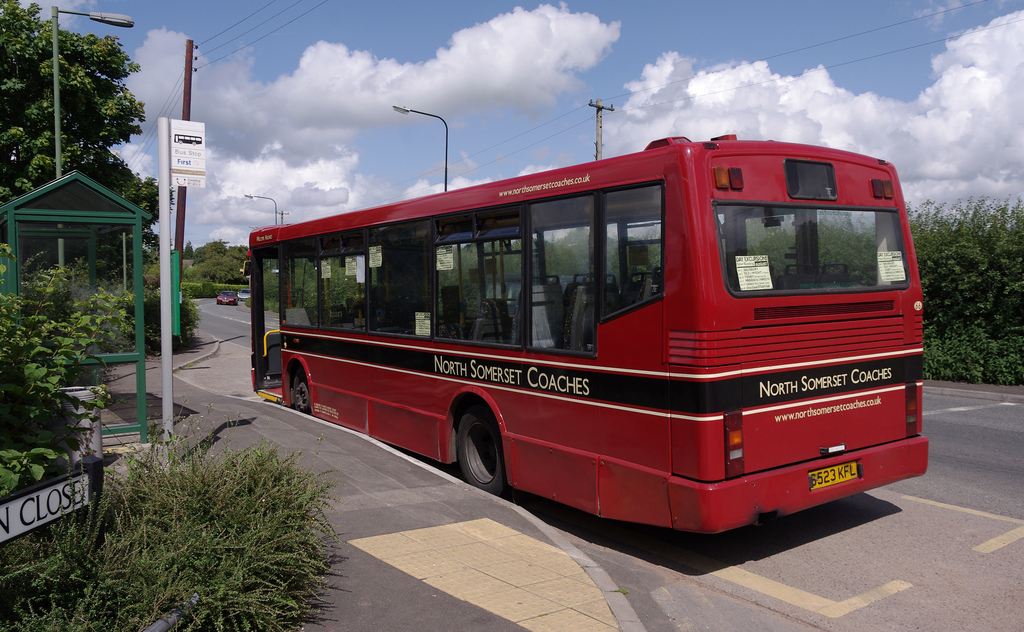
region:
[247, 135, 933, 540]
bus is red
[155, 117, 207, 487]
bus sign is attached to pole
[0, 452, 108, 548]
sign is inside of bushes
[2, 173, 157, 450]
bus stop bench is green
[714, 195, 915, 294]
window apart of bus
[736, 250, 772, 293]
paper is attached to bus window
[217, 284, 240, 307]
car is red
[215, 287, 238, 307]
red car driving on the road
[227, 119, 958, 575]
the bus is red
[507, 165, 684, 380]
a window of a bus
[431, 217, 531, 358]
a window of a bus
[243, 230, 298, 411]
the door on front the bus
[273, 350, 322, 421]
front wheel of a tire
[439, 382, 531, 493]
back wheel of a tire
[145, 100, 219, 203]
a sign on a pole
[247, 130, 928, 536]
red tour bus parked at a street curb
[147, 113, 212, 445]
bus stop signage on the walkway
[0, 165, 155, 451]
bus bench stop on the sidewalk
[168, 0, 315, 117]
wooden telephone pole and wires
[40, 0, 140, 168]
street light and pole over the walkway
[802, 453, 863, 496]
the buses license plate displayed on the bumper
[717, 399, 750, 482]
the buses tail and brake lights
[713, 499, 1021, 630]
painted traffic lines on the street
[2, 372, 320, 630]
landscaping and planter on the walkway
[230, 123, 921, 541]
red bus stopped on the street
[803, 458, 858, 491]
yellow license plate with black lettering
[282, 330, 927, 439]
black stripe on the bus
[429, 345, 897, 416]
white lettering on black stripe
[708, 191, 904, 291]
back window of the bus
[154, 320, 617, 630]
sidewalk next to the street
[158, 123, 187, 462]
grey pole sign attached to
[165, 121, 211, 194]
white sign with black text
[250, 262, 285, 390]
door to the bus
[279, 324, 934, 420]
white stripes on the bus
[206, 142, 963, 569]
red and black passenger bus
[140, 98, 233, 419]
black and white bus stop sign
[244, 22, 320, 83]
white clouds in blue sky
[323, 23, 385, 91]
white clouds in blue sky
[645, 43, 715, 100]
white clouds in blue sky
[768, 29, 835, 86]
white clouds in blue sky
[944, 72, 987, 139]
white clouds in blue sky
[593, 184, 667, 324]
A window on a vehicle.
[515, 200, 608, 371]
A window on a vehicle.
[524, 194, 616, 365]
A window on a vehicle.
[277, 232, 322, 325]
A window on a vehicle.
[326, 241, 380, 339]
A window on a vehicle.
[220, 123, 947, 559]
the bus is color red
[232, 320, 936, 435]
the bus has a black stripe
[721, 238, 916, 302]
two sheets of paper on back the bus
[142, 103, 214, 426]
a sign on a gray pole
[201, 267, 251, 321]
a car on the road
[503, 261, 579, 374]
the bus has gray sit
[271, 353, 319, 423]
front wheels of bus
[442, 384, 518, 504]
back wheels of bus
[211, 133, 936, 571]
long red tour bus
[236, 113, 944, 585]
long red tour bus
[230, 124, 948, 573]
long red tour bus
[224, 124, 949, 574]
long red tour bus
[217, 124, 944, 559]
long red tour bus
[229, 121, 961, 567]
long red tour bus